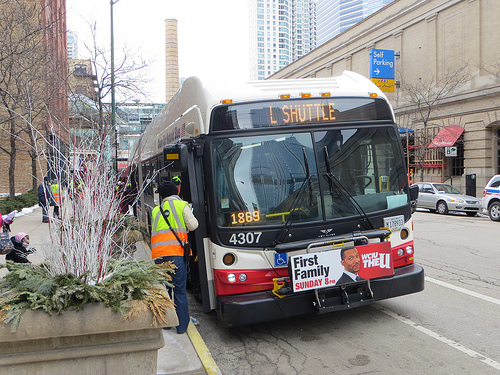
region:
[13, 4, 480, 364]
photograph of a city street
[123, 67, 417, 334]
white city bus stopped at bus stop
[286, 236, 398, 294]
advertisement for a tv show on the bus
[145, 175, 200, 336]
person wearing a safety vest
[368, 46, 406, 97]
sign for a parkig garage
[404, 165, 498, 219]
cars parked on the side of the street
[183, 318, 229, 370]
curb painted yellow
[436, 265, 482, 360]
white lines painted in the street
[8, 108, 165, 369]
planter on sidewalk filled with plants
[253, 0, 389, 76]
tall glass building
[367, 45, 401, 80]
The sign is blue.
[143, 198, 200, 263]
The man is wearing a safety vest.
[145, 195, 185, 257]
The safety vest is yellow and orange.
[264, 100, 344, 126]
The light is on.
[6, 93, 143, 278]
The tree is bare.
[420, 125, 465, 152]
The awning is red.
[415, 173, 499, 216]
The car is parked.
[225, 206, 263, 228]
The numbers are orange.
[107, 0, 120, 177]
The pole is metal.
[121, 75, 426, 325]
The bus is on the street.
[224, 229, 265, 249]
Number 4307 on the bus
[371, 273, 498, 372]
Two white lines on street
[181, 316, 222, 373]
The curb is yellow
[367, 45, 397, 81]
Blue sign with white writing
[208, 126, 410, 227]
Window on front of the bus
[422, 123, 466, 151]
Red awning on a building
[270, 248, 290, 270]
Handicap sign on bus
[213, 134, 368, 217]
Reflections on bus window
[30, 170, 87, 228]
People standing on the sidewalk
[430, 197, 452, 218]
A round black tire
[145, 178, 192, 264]
Man wearing a yellow and orange vest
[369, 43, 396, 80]
Blue sign with white letters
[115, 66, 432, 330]
Public transportation bus parked on the road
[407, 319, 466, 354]
White stripe on the road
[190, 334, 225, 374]
Street curb with yellow paint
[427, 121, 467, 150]
Red awning with white letters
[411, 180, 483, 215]
Gray car parked on the side of the road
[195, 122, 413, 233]
Front window of a bus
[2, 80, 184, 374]
Potted plants on the sidewalk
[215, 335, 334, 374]
Cracks in the road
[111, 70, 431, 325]
A white and red bus.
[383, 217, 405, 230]
A licence plate on a bus.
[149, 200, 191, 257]
An orange, yellow, and grey safety vest.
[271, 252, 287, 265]
A blue and white handicapped sign.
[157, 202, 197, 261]
A black crossbody bag.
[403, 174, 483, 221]
A silver parked car.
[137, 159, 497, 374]
The road.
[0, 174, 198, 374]
The sidewalk.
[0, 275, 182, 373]
A flower planter.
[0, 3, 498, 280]
Trees without any leaves.